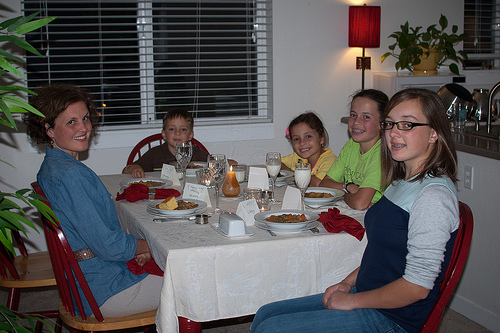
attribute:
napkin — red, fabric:
[315, 205, 365, 242]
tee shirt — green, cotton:
[335, 137, 392, 185]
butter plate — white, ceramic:
[213, 212, 250, 237]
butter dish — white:
[212, 210, 248, 243]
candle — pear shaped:
[169, 167, 259, 208]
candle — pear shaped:
[217, 162, 241, 196]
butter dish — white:
[213, 210, 246, 237]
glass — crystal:
[291, 160, 314, 186]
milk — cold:
[298, 177, 308, 189]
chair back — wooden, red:
[35, 182, 105, 323]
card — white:
[238, 200, 269, 222]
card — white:
[245, 159, 273, 187]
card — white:
[157, 159, 179, 178]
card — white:
[183, 174, 209, 204]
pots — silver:
[442, 73, 496, 117]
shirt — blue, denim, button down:
[33, 145, 143, 307]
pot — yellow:
[409, 49, 439, 73]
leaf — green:
[449, 63, 461, 76]